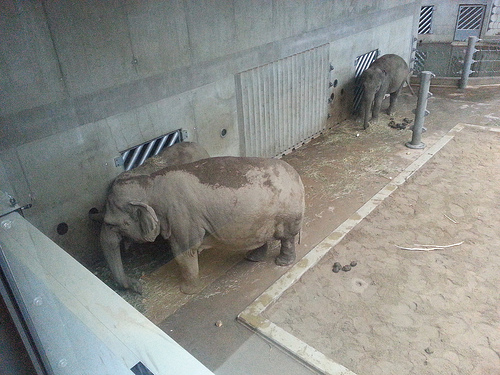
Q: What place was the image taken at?
A: It was taken at the pen.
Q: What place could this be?
A: It is a pen.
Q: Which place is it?
A: It is a pen.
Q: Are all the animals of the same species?
A: Yes, all the animals are elephants.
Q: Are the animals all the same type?
A: Yes, all the animals are elephants.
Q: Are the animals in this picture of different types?
A: No, all the animals are elephants.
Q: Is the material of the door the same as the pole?
A: Yes, both the door and the pole are made of metal.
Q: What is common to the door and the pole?
A: The material, both the door and the pole are metallic.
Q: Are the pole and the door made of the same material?
A: Yes, both the pole and the door are made of metal.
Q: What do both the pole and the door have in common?
A: The material, both the pole and the door are metallic.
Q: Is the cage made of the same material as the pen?
A: Yes, both the cage and the pen are made of concrete.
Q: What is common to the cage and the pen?
A: The material, both the cage and the pen are concrete.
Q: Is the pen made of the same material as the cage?
A: Yes, both the pen and the cage are made of cement.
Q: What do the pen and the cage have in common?
A: The material, both the pen and the cage are concrete.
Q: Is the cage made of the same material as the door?
A: No, the cage is made of concrete and the door is made of metal.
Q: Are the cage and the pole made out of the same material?
A: No, the cage is made of concrete and the pole is made of metal.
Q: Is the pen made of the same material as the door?
A: No, the pen is made of cement and the door is made of metal.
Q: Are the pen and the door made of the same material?
A: No, the pen is made of cement and the door is made of metal.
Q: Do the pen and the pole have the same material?
A: No, the pen is made of concrete and the pole is made of metal.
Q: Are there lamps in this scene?
A: No, there are no lamps.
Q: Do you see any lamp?
A: No, there are no lamps.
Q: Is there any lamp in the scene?
A: No, there are no lamps.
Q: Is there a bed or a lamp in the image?
A: No, there are no lamps or beds.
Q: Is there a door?
A: Yes, there is a door.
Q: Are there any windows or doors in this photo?
A: Yes, there is a door.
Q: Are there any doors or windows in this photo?
A: Yes, there is a door.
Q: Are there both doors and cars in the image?
A: No, there is a door but no cars.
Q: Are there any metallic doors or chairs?
A: Yes, there is a metal door.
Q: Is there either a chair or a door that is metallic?
A: Yes, the door is metallic.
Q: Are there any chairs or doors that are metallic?
A: Yes, the door is metallic.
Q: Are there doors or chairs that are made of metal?
A: Yes, the door is made of metal.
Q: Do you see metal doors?
A: Yes, there is a metal door.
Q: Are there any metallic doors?
A: Yes, there is a metal door.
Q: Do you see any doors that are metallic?
A: Yes, there is a door that is metallic.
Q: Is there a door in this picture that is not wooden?
A: Yes, there is a metallic door.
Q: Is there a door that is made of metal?
A: Yes, there is a door that is made of metal.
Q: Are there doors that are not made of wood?
A: Yes, there is a door that is made of metal.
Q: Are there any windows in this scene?
A: No, there are no windows.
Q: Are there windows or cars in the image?
A: No, there are no windows or cars.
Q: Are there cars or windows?
A: No, there are no windows or cars.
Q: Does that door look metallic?
A: Yes, the door is metallic.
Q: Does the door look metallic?
A: Yes, the door is metallic.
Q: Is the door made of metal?
A: Yes, the door is made of metal.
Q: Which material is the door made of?
A: The door is made of metal.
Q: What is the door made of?
A: The door is made of metal.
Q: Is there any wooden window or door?
A: No, there is a door but it is metallic.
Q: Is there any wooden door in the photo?
A: No, there is a door but it is metallic.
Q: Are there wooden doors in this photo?
A: No, there is a door but it is metallic.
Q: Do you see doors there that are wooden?
A: No, there is a door but it is metallic.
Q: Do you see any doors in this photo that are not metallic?
A: No, there is a door but it is metallic.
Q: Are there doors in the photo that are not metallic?
A: No, there is a door but it is metallic.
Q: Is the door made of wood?
A: No, the door is made of metal.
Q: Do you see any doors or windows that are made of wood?
A: No, there is a door but it is made of metal.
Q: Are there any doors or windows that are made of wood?
A: No, there is a door but it is made of metal.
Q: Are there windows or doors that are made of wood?
A: No, there is a door but it is made of metal.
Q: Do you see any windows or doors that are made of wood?
A: No, there is a door but it is made of metal.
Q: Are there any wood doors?
A: No, there is a door but it is made of metal.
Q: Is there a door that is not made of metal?
A: No, there is a door but it is made of metal.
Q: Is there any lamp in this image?
A: No, there are no lamps.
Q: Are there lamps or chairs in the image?
A: No, there are no lamps or chairs.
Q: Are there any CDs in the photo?
A: No, there are no cds.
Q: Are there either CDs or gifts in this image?
A: No, there are no CDs or gifts.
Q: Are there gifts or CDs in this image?
A: No, there are no CDs or gifts.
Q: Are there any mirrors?
A: No, there are no mirrors.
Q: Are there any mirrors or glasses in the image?
A: No, there are no mirrors or glasses.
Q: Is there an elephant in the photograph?
A: Yes, there is an elephant.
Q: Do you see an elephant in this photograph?
A: Yes, there is an elephant.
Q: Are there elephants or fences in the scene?
A: Yes, there is an elephant.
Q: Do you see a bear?
A: No, there are no bears.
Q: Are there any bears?
A: No, there are no bears.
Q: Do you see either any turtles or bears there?
A: No, there are no bears or turtles.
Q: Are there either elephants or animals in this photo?
A: Yes, there is an elephant.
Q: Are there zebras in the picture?
A: No, there are no zebras.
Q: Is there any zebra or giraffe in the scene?
A: No, there are no zebras or giraffes.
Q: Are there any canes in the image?
A: No, there are no canes.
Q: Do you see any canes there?
A: No, there are no canes.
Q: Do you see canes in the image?
A: No, there are no canes.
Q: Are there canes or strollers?
A: No, there are no canes or strollers.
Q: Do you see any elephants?
A: Yes, there is an elephant.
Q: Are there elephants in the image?
A: Yes, there is an elephant.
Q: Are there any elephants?
A: Yes, there is an elephant.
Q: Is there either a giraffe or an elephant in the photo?
A: Yes, there is an elephant.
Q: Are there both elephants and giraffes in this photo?
A: No, there is an elephant but no giraffes.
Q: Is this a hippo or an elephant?
A: This is an elephant.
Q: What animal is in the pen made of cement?
A: The elephant is in the pen.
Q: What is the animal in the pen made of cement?
A: The animal is an elephant.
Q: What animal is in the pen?
A: The animal is an elephant.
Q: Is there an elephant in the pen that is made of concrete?
A: Yes, there is an elephant in the pen.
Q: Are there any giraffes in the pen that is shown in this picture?
A: No, there is an elephant in the pen.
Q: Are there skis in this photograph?
A: No, there are no skis.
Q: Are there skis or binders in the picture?
A: No, there are no skis or binders.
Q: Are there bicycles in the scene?
A: No, there are no bicycles.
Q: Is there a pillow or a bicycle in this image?
A: No, there are no bicycles or pillows.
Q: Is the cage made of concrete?
A: Yes, the cage is made of concrete.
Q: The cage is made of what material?
A: The cage is made of cement.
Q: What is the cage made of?
A: The cage is made of concrete.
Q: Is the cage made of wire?
A: No, the cage is made of concrete.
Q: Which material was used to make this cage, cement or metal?
A: The cage is made of cement.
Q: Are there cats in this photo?
A: No, there are no cats.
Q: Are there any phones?
A: No, there are no phones.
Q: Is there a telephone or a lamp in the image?
A: No, there are no phones or lamps.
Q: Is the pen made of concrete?
A: Yes, the pen is made of concrete.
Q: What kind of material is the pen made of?
A: The pen is made of cement.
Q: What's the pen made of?
A: The pen is made of concrete.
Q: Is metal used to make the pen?
A: No, the pen is made of concrete.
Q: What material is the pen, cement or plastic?
A: The pen is made of cement.